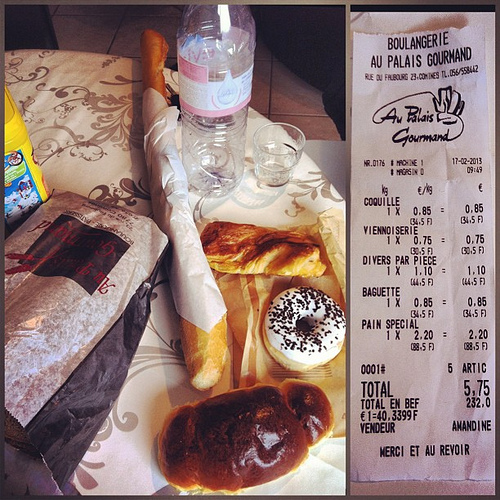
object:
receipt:
[350, 10, 498, 500]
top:
[192, 410, 300, 465]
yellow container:
[4, 87, 51, 228]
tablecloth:
[0, 51, 348, 496]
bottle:
[175, 0, 255, 197]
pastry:
[3, 29, 345, 491]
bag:
[4, 187, 169, 427]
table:
[2, 0, 346, 495]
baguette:
[140, 28, 229, 391]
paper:
[142, 87, 229, 332]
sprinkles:
[273, 299, 295, 335]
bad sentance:
[4, 219, 117, 295]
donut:
[262, 284, 347, 373]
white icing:
[264, 285, 346, 365]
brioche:
[157, 377, 335, 495]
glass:
[251, 122, 306, 186]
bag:
[198, 208, 346, 438]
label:
[178, 54, 254, 118]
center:
[295, 314, 317, 334]